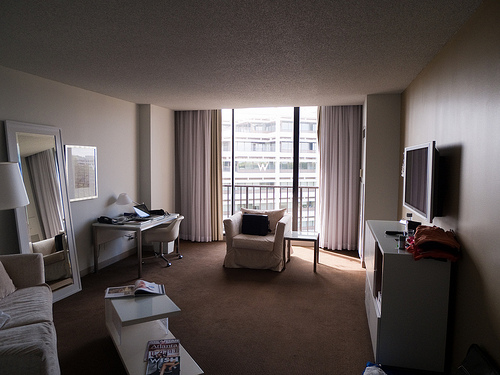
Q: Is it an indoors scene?
A: Yes, it is indoors.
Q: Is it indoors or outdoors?
A: It is indoors.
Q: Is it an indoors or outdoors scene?
A: It is indoors.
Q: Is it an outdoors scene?
A: No, it is indoors.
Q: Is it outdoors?
A: No, it is indoors.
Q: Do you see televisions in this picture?
A: Yes, there is a television.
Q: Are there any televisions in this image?
A: Yes, there is a television.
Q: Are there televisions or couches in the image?
A: Yes, there is a television.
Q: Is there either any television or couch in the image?
A: Yes, there is a television.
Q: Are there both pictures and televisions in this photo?
A: Yes, there are both a television and a picture.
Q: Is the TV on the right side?
A: Yes, the TV is on the right of the image.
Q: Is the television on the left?
A: No, the television is on the right of the image.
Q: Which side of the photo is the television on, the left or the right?
A: The television is on the right of the image.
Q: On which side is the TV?
A: The TV is on the right of the image.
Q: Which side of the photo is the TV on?
A: The TV is on the right of the image.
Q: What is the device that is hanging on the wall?
A: The device is a television.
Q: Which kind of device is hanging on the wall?
A: The device is a television.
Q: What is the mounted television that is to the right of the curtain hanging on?
A: The TV is hanging on the wall.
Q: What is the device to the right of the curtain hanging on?
A: The TV is hanging on the wall.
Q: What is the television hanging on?
A: The TV is hanging on the wall.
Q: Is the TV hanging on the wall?
A: Yes, the TV is hanging on the wall.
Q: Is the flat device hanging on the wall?
A: Yes, the TV is hanging on the wall.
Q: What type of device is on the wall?
A: The device is a television.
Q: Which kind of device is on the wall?
A: The device is a television.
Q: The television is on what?
A: The television is on the wall.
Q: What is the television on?
A: The television is on the wall.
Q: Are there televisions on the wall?
A: Yes, there is a television on the wall.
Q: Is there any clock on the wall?
A: No, there is a television on the wall.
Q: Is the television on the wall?
A: Yes, the television is on the wall.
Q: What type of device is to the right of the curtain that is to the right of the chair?
A: The device is a television.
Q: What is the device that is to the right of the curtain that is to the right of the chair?
A: The device is a television.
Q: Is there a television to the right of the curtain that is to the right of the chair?
A: Yes, there is a television to the right of the curtain.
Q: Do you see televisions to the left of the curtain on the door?
A: No, the television is to the right of the curtain.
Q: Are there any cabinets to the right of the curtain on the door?
A: No, there is a television to the right of the curtain.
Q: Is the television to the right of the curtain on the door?
A: Yes, the television is to the right of the curtain.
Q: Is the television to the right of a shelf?
A: No, the television is to the right of the curtain.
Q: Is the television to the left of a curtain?
A: No, the television is to the right of a curtain.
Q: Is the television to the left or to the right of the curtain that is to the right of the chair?
A: The television is to the right of the curtain.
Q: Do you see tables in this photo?
A: Yes, there is a table.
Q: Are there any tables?
A: Yes, there is a table.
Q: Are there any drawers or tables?
A: Yes, there is a table.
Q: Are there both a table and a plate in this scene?
A: No, there is a table but no plates.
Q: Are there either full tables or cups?
A: Yes, there is a full table.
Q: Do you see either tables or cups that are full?
A: Yes, the table is full.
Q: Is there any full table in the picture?
A: Yes, there is a full table.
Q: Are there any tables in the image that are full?
A: Yes, there is a table that is full.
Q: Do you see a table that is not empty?
A: Yes, there is an full table.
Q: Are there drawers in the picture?
A: No, there are no drawers.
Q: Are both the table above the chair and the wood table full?
A: Yes, both the table and the table are full.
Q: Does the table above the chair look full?
A: Yes, the table is full.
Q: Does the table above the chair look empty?
A: No, the table is full.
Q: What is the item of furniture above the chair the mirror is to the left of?
A: The piece of furniture is a table.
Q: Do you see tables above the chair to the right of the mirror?
A: Yes, there is a table above the chair.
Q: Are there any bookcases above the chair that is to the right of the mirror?
A: No, there is a table above the chair.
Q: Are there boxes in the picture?
A: No, there are no boxes.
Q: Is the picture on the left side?
A: Yes, the picture is on the left of the image.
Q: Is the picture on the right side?
A: No, the picture is on the left of the image.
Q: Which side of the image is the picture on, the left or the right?
A: The picture is on the left of the image.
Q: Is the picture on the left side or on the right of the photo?
A: The picture is on the left of the image.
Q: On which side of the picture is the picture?
A: The picture is on the left of the image.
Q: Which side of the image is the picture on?
A: The picture is on the left of the image.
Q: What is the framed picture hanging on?
A: The picture is hanging on the wall.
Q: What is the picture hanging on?
A: The picture is hanging on the wall.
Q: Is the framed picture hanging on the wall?
A: Yes, the picture is hanging on the wall.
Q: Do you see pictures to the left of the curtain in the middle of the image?
A: Yes, there is a picture to the left of the curtain.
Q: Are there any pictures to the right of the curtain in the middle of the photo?
A: No, the picture is to the left of the curtain.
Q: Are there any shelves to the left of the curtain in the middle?
A: No, there is a picture to the left of the curtain.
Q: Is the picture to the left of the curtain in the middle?
A: Yes, the picture is to the left of the curtain.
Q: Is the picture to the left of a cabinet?
A: No, the picture is to the left of the curtain.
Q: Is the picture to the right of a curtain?
A: No, the picture is to the left of a curtain.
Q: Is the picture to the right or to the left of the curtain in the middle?
A: The picture is to the left of the curtain.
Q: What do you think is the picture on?
A: The picture is on the wall.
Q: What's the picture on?
A: The picture is on the wall.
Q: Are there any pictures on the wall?
A: Yes, there is a picture on the wall.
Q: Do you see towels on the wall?
A: No, there is a picture on the wall.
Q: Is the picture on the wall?
A: Yes, the picture is on the wall.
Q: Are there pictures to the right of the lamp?
A: Yes, there is a picture to the right of the lamp.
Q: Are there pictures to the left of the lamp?
A: No, the picture is to the right of the lamp.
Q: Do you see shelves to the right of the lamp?
A: No, there is a picture to the right of the lamp.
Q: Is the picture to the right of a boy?
A: No, the picture is to the right of the lamp.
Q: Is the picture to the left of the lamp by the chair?
A: No, the picture is to the right of the lamp.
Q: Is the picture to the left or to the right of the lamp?
A: The picture is to the right of the lamp.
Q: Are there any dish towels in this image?
A: No, there are no dish towels.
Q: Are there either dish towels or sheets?
A: No, there are no dish towels or sheets.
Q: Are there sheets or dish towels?
A: No, there are no dish towels or sheets.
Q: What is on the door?
A: The curtain is on the door.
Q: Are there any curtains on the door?
A: Yes, there is a curtain on the door.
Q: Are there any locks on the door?
A: No, there is a curtain on the door.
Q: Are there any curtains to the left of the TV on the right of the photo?
A: Yes, there is a curtain to the left of the TV.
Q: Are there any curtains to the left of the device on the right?
A: Yes, there is a curtain to the left of the TV.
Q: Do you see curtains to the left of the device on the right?
A: Yes, there is a curtain to the left of the TV.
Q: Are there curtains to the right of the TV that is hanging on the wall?
A: No, the curtain is to the left of the TV.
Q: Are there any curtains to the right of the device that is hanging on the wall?
A: No, the curtain is to the left of the TV.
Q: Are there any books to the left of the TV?
A: No, there is a curtain to the left of the TV.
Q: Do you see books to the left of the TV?
A: No, there is a curtain to the left of the TV.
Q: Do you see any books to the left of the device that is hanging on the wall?
A: No, there is a curtain to the left of the TV.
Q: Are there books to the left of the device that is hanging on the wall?
A: No, there is a curtain to the left of the TV.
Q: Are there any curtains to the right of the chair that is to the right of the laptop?
A: Yes, there is a curtain to the right of the chair.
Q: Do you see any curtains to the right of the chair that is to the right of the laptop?
A: Yes, there is a curtain to the right of the chair.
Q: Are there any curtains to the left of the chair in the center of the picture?
A: No, the curtain is to the right of the chair.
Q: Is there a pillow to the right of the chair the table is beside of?
A: No, there is a curtain to the right of the chair.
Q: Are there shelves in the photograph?
A: No, there are no shelves.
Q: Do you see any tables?
A: Yes, there is a table.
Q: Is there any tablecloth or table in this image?
A: Yes, there is a table.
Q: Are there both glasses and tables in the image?
A: No, there is a table but no glasses.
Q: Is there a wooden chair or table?
A: Yes, there is a wood table.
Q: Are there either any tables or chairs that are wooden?
A: Yes, the table is wooden.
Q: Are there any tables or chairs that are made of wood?
A: Yes, the table is made of wood.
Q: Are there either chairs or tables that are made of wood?
A: Yes, the table is made of wood.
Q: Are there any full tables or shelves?
A: Yes, there is a full table.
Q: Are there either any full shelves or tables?
A: Yes, there is a full table.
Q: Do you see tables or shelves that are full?
A: Yes, the table is full.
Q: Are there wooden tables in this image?
A: Yes, there is a wood table.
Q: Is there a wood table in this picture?
A: Yes, there is a wood table.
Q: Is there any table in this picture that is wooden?
A: Yes, there is a table that is wooden.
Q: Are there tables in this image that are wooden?
A: Yes, there is a table that is wooden.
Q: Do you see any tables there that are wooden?
A: Yes, there is a table that is wooden.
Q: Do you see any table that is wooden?
A: Yes, there is a table that is wooden.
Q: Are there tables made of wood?
A: Yes, there is a table that is made of wood.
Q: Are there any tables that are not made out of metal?
A: Yes, there is a table that is made of wood.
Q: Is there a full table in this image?
A: Yes, there is a full table.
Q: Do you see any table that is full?
A: Yes, there is a table that is full.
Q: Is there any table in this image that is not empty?
A: Yes, there is an full table.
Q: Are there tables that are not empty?
A: Yes, there is an full table.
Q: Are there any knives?
A: No, there are no knives.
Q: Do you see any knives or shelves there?
A: No, there are no knives or shelves.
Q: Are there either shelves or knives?
A: No, there are no knives or shelves.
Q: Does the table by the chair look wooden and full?
A: Yes, the table is wooden and full.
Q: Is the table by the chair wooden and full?
A: Yes, the table is wooden and full.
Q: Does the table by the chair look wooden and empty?
A: No, the table is wooden but full.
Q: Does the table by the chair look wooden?
A: Yes, the table is wooden.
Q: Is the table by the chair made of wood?
A: Yes, the table is made of wood.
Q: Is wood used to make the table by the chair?
A: Yes, the table is made of wood.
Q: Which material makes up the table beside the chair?
A: The table is made of wood.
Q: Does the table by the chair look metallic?
A: No, the table is wooden.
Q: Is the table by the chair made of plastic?
A: No, the table is made of wood.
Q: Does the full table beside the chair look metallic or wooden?
A: The table is wooden.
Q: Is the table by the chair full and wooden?
A: Yes, the table is full and wooden.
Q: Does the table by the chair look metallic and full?
A: No, the table is full but wooden.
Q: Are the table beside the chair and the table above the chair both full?
A: Yes, both the table and the table are full.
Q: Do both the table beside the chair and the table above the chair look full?
A: Yes, both the table and the table are full.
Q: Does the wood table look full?
A: Yes, the table is full.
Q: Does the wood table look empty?
A: No, the table is full.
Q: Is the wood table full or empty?
A: The table is full.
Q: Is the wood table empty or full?
A: The table is full.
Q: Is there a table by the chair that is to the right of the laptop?
A: Yes, there is a table by the chair.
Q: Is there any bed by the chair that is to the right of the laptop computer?
A: No, there is a table by the chair.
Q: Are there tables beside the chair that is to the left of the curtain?
A: Yes, there is a table beside the chair.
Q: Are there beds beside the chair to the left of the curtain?
A: No, there is a table beside the chair.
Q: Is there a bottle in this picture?
A: No, there are no bottles.